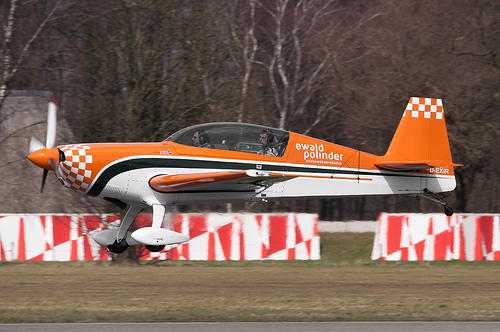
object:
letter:
[309, 142, 315, 153]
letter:
[302, 150, 308, 160]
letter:
[308, 149, 316, 163]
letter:
[322, 150, 329, 160]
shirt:
[262, 148, 275, 158]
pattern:
[59, 137, 95, 192]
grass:
[13, 261, 464, 312]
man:
[190, 123, 212, 147]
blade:
[40, 93, 60, 151]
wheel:
[106, 238, 131, 255]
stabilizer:
[386, 90, 460, 155]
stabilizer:
[371, 159, 465, 178]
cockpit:
[162, 119, 291, 159]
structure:
[130, 203, 187, 246]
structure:
[88, 227, 135, 248]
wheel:
[145, 241, 166, 251]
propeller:
[26, 89, 81, 196]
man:
[254, 125, 279, 160]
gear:
[90, 201, 189, 254]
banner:
[0, 209, 500, 265]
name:
[289, 137, 347, 165]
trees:
[106, 14, 386, 137]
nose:
[29, 128, 95, 190]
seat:
[253, 125, 292, 150]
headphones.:
[253, 128, 278, 145]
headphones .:
[188, 126, 208, 138]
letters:
[429, 166, 449, 176]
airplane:
[24, 96, 460, 255]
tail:
[375, 87, 465, 205]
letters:
[294, 139, 302, 149]